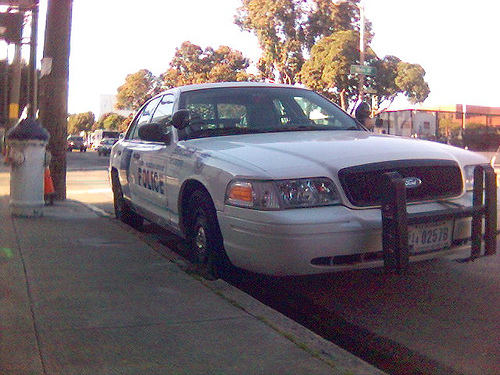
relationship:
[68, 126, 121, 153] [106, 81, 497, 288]
cars driving behind police car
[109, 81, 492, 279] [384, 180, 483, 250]
car has a batting ram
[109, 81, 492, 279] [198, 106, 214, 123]
car has a caged enclosure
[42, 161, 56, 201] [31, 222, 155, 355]
cone on sidewalk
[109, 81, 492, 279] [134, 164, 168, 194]
car has lettering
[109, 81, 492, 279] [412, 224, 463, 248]
car has a license plate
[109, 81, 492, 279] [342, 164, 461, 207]
car has a car grill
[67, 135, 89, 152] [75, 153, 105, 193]
cars driving down road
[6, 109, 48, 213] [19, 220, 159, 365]
fire hydrant on sidewalk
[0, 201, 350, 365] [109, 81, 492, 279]
cement sidewalk beside car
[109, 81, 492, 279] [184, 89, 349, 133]
car has a windshield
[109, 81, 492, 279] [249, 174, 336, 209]
car has a headlight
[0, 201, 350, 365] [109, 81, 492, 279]
cement sidewalk near a car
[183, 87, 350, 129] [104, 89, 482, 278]
windshield on a car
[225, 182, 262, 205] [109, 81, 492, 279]
right blinker on a car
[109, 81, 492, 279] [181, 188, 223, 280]
car has a right front tire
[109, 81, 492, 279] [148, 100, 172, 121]
car has a side window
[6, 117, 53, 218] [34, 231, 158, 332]
fire hydrant on a sidewalk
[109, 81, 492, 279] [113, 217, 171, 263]
car by curbside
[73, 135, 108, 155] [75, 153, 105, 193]
cars driving down a road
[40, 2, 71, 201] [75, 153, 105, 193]
brown pole by a road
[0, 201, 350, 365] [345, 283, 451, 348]
cement sidewalk by a street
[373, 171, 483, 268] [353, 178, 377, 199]
cage in front of car grill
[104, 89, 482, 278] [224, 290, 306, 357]
car parked by curb